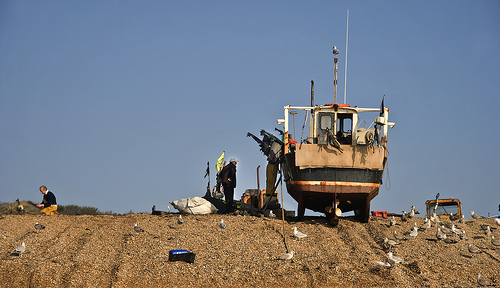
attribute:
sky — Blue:
[0, 0, 499, 217]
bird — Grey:
[389, 247, 423, 277]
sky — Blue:
[8, 5, 237, 122]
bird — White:
[488, 233, 499, 252]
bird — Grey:
[474, 272, 489, 285]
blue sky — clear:
[0, 0, 496, 215]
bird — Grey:
[13, 240, 27, 259]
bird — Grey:
[279, 250, 295, 265]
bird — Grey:
[288, 226, 308, 241]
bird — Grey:
[380, 235, 398, 248]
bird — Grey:
[435, 227, 447, 242]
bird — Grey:
[281, 220, 309, 266]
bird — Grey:
[464, 234, 488, 262]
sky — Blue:
[401, 32, 473, 84]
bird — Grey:
[287, 222, 306, 242]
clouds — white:
[402, 22, 447, 47]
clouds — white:
[93, 74, 270, 194]